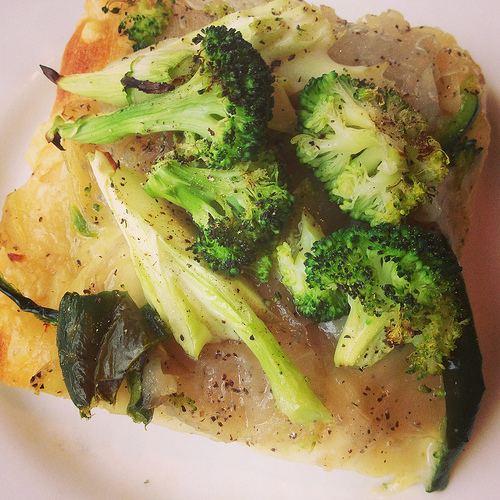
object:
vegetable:
[54, 283, 180, 430]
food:
[0, 0, 490, 498]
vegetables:
[287, 68, 451, 226]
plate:
[0, 0, 498, 500]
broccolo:
[300, 219, 466, 381]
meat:
[401, 27, 463, 90]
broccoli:
[289, 67, 451, 228]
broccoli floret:
[357, 106, 409, 178]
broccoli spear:
[57, 26, 277, 166]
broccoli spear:
[141, 150, 294, 279]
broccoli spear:
[288, 69, 458, 229]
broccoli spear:
[302, 220, 469, 375]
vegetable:
[53, 26, 273, 163]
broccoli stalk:
[332, 321, 382, 366]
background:
[0, 0, 497, 499]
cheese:
[0, 157, 122, 288]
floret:
[57, 25, 282, 171]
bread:
[51, 11, 119, 118]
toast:
[0, 1, 490, 495]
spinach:
[53, 287, 177, 427]